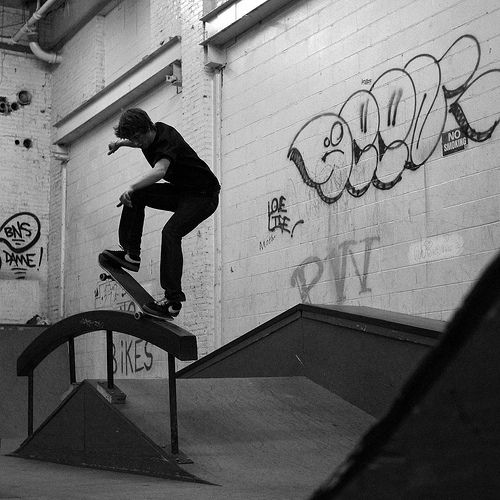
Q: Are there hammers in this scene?
A: No, there are no hammers.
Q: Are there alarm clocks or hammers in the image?
A: No, there are no hammers or alarm clocks.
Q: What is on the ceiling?
A: The pipes are on the ceiling.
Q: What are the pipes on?
A: The pipes are on the ceiling.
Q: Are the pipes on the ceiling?
A: Yes, the pipes are on the ceiling.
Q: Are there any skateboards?
A: Yes, there is a skateboard.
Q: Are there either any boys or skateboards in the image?
A: Yes, there is a skateboard.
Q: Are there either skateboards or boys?
A: Yes, there is a skateboard.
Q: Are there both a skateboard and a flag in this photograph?
A: No, there is a skateboard but no flags.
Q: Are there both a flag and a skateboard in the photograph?
A: No, there is a skateboard but no flags.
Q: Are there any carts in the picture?
A: No, there are no carts.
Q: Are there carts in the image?
A: No, there are no carts.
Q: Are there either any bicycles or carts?
A: No, there are no carts or bicycles.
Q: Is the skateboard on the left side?
A: Yes, the skateboard is on the left of the image.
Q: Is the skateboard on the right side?
A: No, the skateboard is on the left of the image.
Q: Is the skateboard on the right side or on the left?
A: The skateboard is on the left of the image.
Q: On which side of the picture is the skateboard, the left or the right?
A: The skateboard is on the left of the image.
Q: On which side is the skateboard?
A: The skateboard is on the left of the image.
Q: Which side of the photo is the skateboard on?
A: The skateboard is on the left of the image.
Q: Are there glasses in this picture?
A: No, there are no glasses.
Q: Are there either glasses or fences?
A: No, there are no glasses or fences.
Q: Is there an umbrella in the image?
A: No, there are no umbrellas.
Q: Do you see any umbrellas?
A: No, there are no umbrellas.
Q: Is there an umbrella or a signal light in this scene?
A: No, there are no umbrellas or traffic lights.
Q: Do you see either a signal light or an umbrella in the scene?
A: No, there are no umbrellas or traffic lights.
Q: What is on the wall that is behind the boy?
A: The graffiti is on the wall.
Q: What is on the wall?
A: The graffiti is on the wall.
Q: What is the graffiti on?
A: The graffiti is on the wall.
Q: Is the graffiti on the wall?
A: Yes, the graffiti is on the wall.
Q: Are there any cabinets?
A: No, there are no cabinets.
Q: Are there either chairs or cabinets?
A: No, there are no cabinets or chairs.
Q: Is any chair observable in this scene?
A: No, there are no chairs.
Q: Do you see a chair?
A: No, there are no chairs.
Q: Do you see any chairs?
A: No, there are no chairs.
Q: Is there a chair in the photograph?
A: No, there are no chairs.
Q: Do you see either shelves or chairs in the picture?
A: No, there are no chairs or shelves.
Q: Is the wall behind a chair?
A: No, the wall is behind the boy.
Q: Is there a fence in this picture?
A: No, there are no fences.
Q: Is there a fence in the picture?
A: No, there are no fences.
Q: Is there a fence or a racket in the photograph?
A: No, there are no fences or rackets.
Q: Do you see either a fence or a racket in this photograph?
A: No, there are no fences or rackets.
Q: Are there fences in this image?
A: No, there are no fences.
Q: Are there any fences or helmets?
A: No, there are no fences or helmets.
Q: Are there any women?
A: No, there are no women.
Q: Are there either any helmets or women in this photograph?
A: No, there are no women or helmets.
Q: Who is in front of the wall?
A: The boy is in front of the wall.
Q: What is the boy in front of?
A: The boy is in front of the wall.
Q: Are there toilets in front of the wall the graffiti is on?
A: No, there is a boy in front of the wall.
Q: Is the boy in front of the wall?
A: Yes, the boy is in front of the wall.